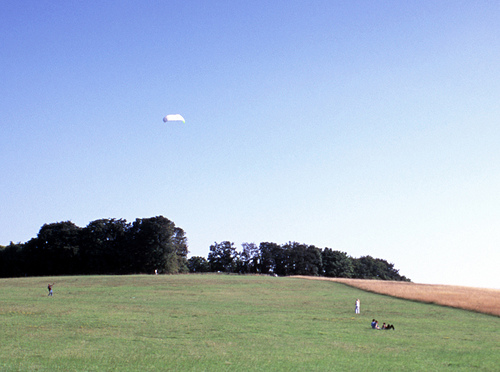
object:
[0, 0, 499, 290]
sky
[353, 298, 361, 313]
person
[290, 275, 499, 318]
grass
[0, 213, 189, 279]
tree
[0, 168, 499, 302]
distance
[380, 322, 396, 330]
people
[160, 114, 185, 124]
parachute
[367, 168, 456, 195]
streak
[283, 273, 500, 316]
patch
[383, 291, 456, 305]
line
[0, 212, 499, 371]
field